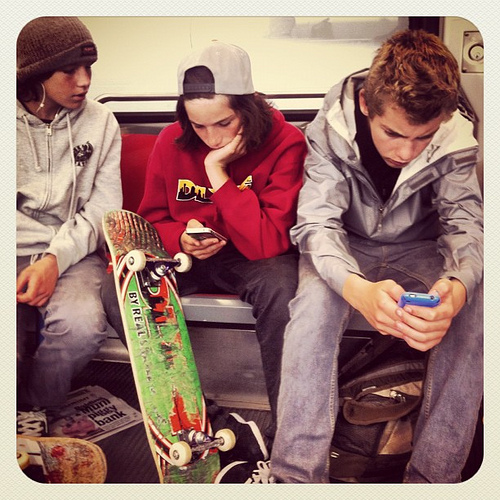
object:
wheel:
[123, 247, 148, 273]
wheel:
[171, 250, 193, 277]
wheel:
[212, 426, 237, 453]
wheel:
[167, 439, 193, 469]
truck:
[144, 253, 176, 264]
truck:
[188, 437, 223, 456]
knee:
[53, 293, 112, 342]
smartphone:
[182, 226, 227, 251]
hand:
[177, 217, 226, 261]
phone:
[396, 289, 443, 315]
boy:
[267, 26, 486, 488]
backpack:
[325, 329, 431, 484]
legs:
[267, 254, 355, 485]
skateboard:
[98, 207, 239, 484]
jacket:
[287, 63, 484, 311]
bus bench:
[76, 93, 384, 417]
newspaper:
[66, 382, 149, 445]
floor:
[71, 357, 278, 486]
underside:
[101, 207, 222, 483]